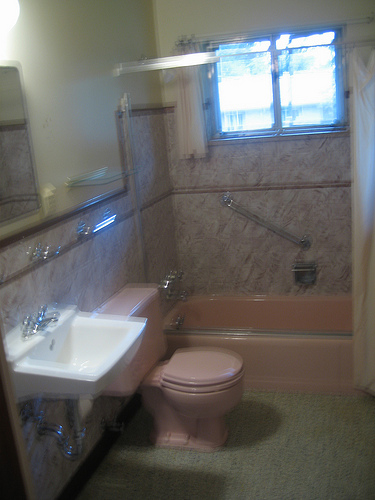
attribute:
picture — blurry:
[2, 1, 374, 499]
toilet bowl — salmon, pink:
[152, 348, 245, 452]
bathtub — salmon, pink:
[165, 293, 351, 392]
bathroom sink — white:
[3, 304, 150, 402]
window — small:
[207, 24, 346, 149]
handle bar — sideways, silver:
[218, 193, 313, 254]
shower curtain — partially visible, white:
[343, 50, 374, 401]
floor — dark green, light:
[75, 391, 374, 499]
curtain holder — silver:
[113, 38, 373, 78]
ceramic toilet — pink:
[97, 286, 246, 454]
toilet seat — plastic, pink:
[163, 349, 245, 393]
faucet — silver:
[159, 272, 183, 304]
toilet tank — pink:
[98, 286, 171, 402]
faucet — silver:
[20, 303, 62, 335]